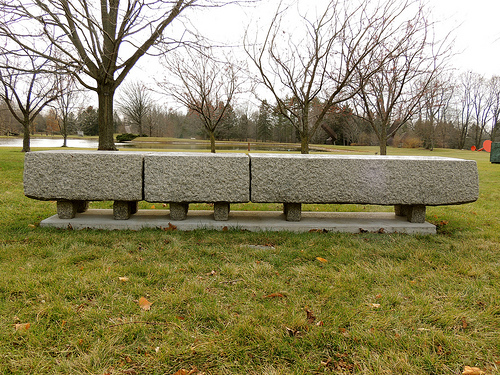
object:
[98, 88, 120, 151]
treetrunk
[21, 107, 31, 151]
treetrunk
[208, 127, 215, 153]
treetrunk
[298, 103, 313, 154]
treetrunk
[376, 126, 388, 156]
treetrunk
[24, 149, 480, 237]
stone design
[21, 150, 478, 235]
concrete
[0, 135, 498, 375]
grass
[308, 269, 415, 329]
orange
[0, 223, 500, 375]
leaf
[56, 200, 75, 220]
leg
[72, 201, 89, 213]
leg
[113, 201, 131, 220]
leg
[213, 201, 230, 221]
leg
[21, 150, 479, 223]
bench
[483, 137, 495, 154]
object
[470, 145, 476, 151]
object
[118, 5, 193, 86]
branch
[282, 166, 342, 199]
structure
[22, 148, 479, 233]
stone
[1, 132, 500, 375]
field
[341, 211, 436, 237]
slab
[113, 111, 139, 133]
house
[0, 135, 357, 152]
water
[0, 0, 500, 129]
sky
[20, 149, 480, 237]
stone bench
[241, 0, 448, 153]
bare tree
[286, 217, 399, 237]
shadow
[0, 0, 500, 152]
trees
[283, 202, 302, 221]
leg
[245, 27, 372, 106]
branches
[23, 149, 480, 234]
block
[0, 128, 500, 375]
ground